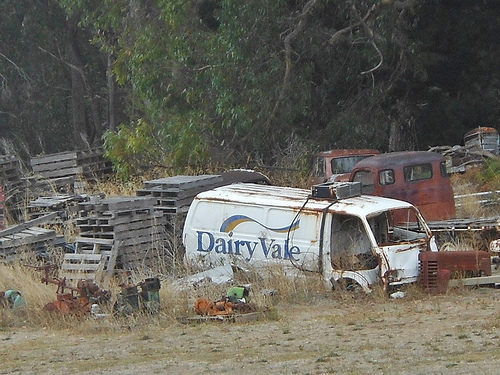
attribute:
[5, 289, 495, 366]
passage — open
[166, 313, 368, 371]
grass — overgrown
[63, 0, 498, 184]
vegetation — background vegetation, thick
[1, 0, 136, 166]
vegetation — thick, background vegetation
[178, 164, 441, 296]
truck — white, scrap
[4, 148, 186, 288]
heaped parts — gray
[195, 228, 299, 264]
brand — blue, printed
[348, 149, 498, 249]
brown truck — old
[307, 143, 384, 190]
brown truck — old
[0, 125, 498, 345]
dump — neglected car dump